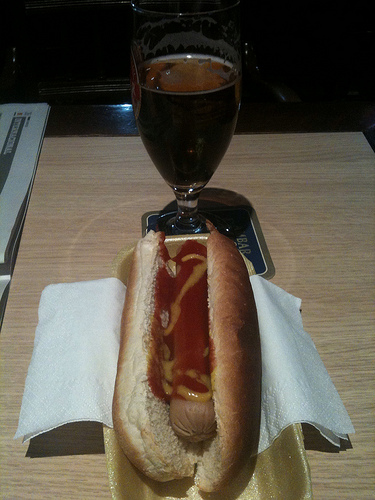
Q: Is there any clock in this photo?
A: No, there are no clocks.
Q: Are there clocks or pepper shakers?
A: No, there are no clocks or pepper shakers.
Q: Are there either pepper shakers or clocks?
A: No, there are no clocks or pepper shakers.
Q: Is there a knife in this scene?
A: No, there are no knives.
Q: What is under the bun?
A: The napkin is under the bun.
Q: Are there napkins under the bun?
A: Yes, there is a napkin under the bun.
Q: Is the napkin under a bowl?
A: No, the napkin is under a bun.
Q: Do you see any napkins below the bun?
A: Yes, there is a napkin below the bun.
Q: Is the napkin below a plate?
A: No, the napkin is below the bun.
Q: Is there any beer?
A: Yes, there is beer.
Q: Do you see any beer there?
A: Yes, there is beer.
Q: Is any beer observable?
A: Yes, there is beer.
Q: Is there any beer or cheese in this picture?
A: Yes, there is beer.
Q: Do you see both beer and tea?
A: No, there is beer but no tea.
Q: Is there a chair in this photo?
A: No, there are no chairs.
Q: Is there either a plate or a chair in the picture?
A: No, there are no chairs or plates.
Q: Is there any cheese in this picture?
A: Yes, there is cheese.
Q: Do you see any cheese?
A: Yes, there is cheese.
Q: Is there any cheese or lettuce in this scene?
A: Yes, there is cheese.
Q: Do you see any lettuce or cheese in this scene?
A: Yes, there is cheese.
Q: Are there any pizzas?
A: No, there are no pizzas.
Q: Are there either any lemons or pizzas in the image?
A: No, there are no pizzas or lemons.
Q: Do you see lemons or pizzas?
A: No, there are no pizzas or lemons.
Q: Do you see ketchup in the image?
A: Yes, there is ketchup.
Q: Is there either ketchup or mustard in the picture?
A: Yes, there is ketchup.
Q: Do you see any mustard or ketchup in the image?
A: Yes, there is ketchup.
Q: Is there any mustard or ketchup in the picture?
A: Yes, there is ketchup.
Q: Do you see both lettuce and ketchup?
A: No, there is ketchup but no lettuce.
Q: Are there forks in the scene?
A: No, there are no forks.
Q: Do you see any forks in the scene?
A: No, there are no forks.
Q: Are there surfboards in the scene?
A: No, there are no surfboards.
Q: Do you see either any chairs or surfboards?
A: No, there are no surfboards or chairs.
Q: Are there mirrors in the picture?
A: No, there are no mirrors.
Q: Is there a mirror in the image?
A: No, there are no mirrors.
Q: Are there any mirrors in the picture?
A: No, there are no mirrors.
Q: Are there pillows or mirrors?
A: No, there are no mirrors or pillows.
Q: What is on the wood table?
A: The glass is on the table.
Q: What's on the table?
A: The glass is on the table.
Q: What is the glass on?
A: The glass is on the table.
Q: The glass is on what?
A: The glass is on the table.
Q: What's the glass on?
A: The glass is on the table.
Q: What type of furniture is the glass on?
A: The glass is on the table.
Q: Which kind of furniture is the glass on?
A: The glass is on the table.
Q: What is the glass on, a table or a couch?
A: The glass is on a table.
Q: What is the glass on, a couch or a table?
A: The glass is on a table.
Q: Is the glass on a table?
A: Yes, the glass is on a table.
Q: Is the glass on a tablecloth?
A: No, the glass is on a table.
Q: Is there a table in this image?
A: Yes, there is a table.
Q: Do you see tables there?
A: Yes, there is a table.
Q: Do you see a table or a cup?
A: Yes, there is a table.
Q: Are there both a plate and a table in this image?
A: No, there is a table but no plates.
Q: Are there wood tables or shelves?
A: Yes, there is a wood table.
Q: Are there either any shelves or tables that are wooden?
A: Yes, the table is wooden.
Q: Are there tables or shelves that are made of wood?
A: Yes, the table is made of wood.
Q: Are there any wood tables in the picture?
A: Yes, there is a wood table.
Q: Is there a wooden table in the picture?
A: Yes, there is a wood table.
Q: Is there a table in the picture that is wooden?
A: Yes, there is a table that is wooden.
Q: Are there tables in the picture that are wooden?
A: Yes, there is a table that is wooden.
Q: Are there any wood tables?
A: Yes, there is a table that is made of wood.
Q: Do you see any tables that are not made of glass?
A: Yes, there is a table that is made of wood.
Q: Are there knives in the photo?
A: No, there are no knives.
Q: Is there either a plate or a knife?
A: No, there are no knives or plates.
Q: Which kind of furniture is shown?
A: The furniture is a table.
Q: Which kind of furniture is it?
A: The piece of furniture is a table.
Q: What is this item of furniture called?
A: This is a table.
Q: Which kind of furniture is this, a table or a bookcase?
A: This is a table.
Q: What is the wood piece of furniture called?
A: The piece of furniture is a table.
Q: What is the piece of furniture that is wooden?
A: The piece of furniture is a table.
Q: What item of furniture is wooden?
A: The piece of furniture is a table.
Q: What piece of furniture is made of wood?
A: The piece of furniture is a table.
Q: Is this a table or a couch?
A: This is a table.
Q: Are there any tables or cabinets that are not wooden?
A: No, there is a table but it is wooden.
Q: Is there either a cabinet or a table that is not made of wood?
A: No, there is a table but it is made of wood.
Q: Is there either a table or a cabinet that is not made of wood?
A: No, there is a table but it is made of wood.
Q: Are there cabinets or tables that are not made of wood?
A: No, there is a table but it is made of wood.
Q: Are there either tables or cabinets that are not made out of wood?
A: No, there is a table but it is made of wood.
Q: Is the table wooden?
A: Yes, the table is wooden.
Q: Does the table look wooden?
A: Yes, the table is wooden.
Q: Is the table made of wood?
A: Yes, the table is made of wood.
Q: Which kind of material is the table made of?
A: The table is made of wood.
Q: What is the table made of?
A: The table is made of wood.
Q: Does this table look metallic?
A: No, the table is wooden.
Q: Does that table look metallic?
A: No, the table is wooden.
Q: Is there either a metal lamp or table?
A: No, there is a table but it is wooden.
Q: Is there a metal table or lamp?
A: No, there is a table but it is wooden.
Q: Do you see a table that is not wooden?
A: No, there is a table but it is wooden.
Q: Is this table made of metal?
A: No, the table is made of wood.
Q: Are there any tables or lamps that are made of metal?
A: No, there is a table but it is made of wood.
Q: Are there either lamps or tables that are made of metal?
A: No, there is a table but it is made of wood.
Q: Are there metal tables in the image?
A: No, there is a table but it is made of wood.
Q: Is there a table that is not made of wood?
A: No, there is a table but it is made of wood.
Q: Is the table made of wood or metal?
A: The table is made of wood.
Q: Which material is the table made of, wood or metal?
A: The table is made of wood.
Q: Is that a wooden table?
A: Yes, that is a wooden table.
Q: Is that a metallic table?
A: No, that is a wooden table.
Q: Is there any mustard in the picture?
A: Yes, there is mustard.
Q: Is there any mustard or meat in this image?
A: Yes, there is mustard.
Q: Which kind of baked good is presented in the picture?
A: The baked good is a bun.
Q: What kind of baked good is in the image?
A: The baked good is a bun.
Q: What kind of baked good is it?
A: The food is a bun.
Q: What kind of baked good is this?
A: This is a bun.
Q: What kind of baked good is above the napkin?
A: The food is a bun.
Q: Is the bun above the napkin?
A: Yes, the bun is above the napkin.